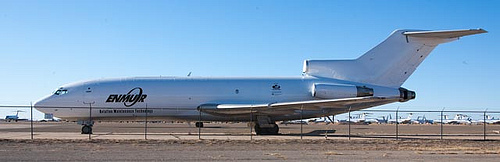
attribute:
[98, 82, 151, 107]
logo — Black 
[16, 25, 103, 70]
clouds — white 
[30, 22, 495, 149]
airplane — big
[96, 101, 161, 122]
letter — black 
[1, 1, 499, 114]
sky — blue 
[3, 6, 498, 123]
sky — clear